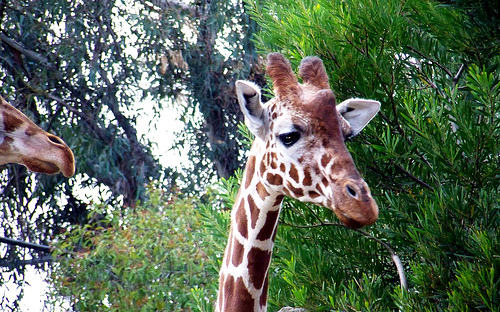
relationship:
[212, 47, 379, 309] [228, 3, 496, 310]
giraffe standing by tree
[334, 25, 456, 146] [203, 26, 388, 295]
tree next to giraffe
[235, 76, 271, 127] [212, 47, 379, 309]
ear of giraffe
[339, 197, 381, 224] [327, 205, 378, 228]
nose and mouth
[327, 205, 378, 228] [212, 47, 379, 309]
mouth of main giraffe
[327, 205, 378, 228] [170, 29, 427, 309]
mouth of main giraffe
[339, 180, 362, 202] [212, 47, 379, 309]
nostril of giraffe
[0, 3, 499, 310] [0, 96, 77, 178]
trees behind giraffe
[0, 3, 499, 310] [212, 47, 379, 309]
trees behind giraffe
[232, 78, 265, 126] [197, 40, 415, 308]
ear of giraffe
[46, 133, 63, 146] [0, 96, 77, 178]
nostril of giraffe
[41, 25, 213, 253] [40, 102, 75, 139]
tree with leaves